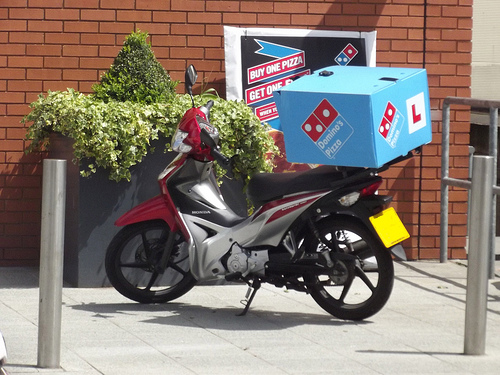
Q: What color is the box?
A: Blue.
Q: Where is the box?
A: On motorcycle.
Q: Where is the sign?
A: On building.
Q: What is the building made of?
A: Brick.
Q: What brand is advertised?
A: Domino's Pizza.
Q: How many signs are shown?
A: One.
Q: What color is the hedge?
A: Green.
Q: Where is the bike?
A: On sidewalk.